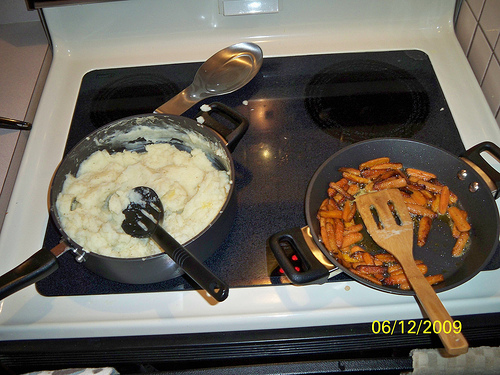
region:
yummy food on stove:
[63, 98, 276, 351]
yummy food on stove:
[307, 138, 490, 364]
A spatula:
[344, 161, 411, 353]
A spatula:
[352, 168, 466, 362]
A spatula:
[348, 228, 435, 372]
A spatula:
[311, 91, 429, 355]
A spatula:
[387, 194, 441, 366]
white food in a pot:
[24, 100, 259, 320]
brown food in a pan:
[309, 149, 459, 310]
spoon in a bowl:
[96, 151, 210, 268]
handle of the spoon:
[389, 252, 453, 339]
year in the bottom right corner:
[420, 306, 471, 345]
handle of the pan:
[4, 231, 65, 308]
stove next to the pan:
[326, 49, 408, 131]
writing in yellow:
[352, 296, 479, 350]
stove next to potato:
[104, 60, 164, 117]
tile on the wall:
[463, 13, 498, 45]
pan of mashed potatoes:
[35, 109, 245, 295]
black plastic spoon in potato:
[121, 184, 191, 266]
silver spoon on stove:
[146, 35, 268, 124]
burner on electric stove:
[297, 51, 431, 156]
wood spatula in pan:
[360, 187, 469, 357]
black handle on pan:
[271, 219, 328, 294]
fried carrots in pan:
[317, 199, 359, 257]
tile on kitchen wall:
[452, 7, 496, 58]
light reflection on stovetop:
[250, 93, 277, 170]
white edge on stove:
[135, 310, 333, 342]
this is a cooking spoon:
[356, 192, 469, 359]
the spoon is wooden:
[388, 234, 404, 249]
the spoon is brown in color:
[389, 233, 408, 248]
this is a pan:
[329, 157, 490, 284]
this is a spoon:
[176, 42, 267, 104]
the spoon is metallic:
[211, 63, 242, 85]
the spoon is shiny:
[221, 52, 250, 59]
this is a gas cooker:
[90, 11, 432, 108]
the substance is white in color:
[87, 213, 105, 230]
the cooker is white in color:
[94, 15, 156, 45]